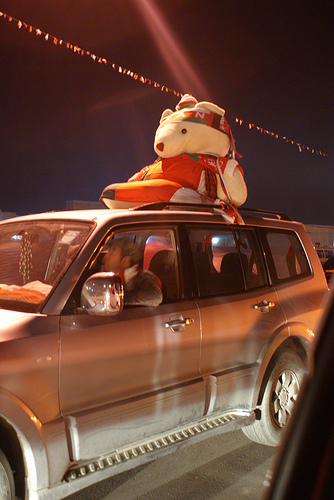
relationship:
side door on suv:
[57, 222, 205, 460] [0, 209, 331, 498]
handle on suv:
[250, 298, 279, 313] [0, 209, 331, 498]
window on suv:
[257, 223, 315, 286] [0, 209, 331, 498]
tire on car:
[229, 329, 324, 452] [2, 210, 327, 458]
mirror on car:
[79, 270, 123, 317] [3, 209, 331, 497]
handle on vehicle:
[250, 298, 279, 313] [1, 202, 326, 494]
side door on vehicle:
[182, 217, 290, 415] [1, 202, 326, 494]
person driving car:
[96, 235, 164, 307] [10, 140, 331, 498]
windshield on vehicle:
[0, 199, 332, 498] [1, 219, 95, 315]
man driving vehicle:
[98, 234, 161, 308] [1, 202, 326, 494]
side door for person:
[57, 222, 205, 460] [96, 235, 164, 307]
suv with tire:
[0, 209, 331, 498] [241, 348, 305, 445]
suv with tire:
[0, 209, 331, 498] [1, 454, 22, 498]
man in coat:
[101, 231, 178, 317] [120, 267, 164, 311]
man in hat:
[101, 231, 178, 317] [105, 231, 148, 262]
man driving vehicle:
[97, 238, 163, 310] [1, 202, 326, 494]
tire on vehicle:
[239, 343, 309, 447] [1, 202, 326, 494]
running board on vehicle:
[63, 397, 257, 498] [1, 202, 326, 494]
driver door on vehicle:
[50, 190, 211, 472] [1, 202, 326, 494]